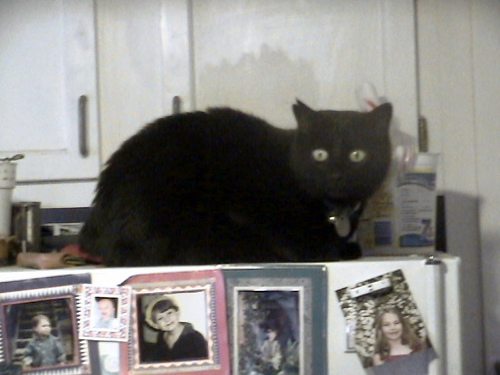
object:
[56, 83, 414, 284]
camera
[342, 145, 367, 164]
eyes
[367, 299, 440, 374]
girl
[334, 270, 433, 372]
picture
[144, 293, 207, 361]
child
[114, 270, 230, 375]
picture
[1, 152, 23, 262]
bucket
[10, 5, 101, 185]
door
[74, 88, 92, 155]
handle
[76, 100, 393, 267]
cat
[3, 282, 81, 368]
pictures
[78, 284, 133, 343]
pictures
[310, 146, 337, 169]
eyes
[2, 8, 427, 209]
cabinets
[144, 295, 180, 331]
cap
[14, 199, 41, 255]
item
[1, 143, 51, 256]
obejcts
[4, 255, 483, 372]
refrigerator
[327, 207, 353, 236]
collar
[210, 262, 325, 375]
photograph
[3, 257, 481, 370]
fridge